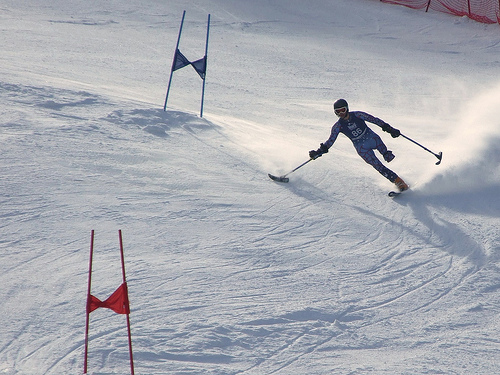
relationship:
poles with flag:
[64, 219, 172, 368] [68, 269, 147, 308]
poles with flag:
[157, 16, 233, 133] [165, 47, 226, 90]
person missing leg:
[308, 98, 410, 194] [351, 135, 409, 165]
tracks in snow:
[347, 261, 481, 334] [173, 156, 412, 360]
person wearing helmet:
[308, 98, 410, 194] [314, 86, 357, 114]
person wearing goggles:
[308, 98, 410, 194] [329, 106, 359, 117]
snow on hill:
[212, 221, 383, 324] [25, 21, 420, 359]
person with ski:
[308, 98, 410, 194] [366, 181, 446, 214]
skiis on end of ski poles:
[251, 160, 293, 194] [219, 105, 330, 216]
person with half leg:
[308, 98, 410, 194] [365, 136, 395, 166]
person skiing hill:
[308, 98, 410, 194] [0, 0, 499, 375]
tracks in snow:
[193, 192, 412, 356] [123, 148, 370, 323]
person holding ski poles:
[288, 69, 445, 208] [252, 129, 336, 201]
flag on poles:
[49, 269, 153, 325] [33, 210, 213, 373]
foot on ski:
[361, 149, 426, 207] [367, 178, 457, 205]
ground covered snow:
[235, 255, 335, 311] [172, 233, 357, 359]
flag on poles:
[154, 22, 204, 104] [165, 8, 286, 124]